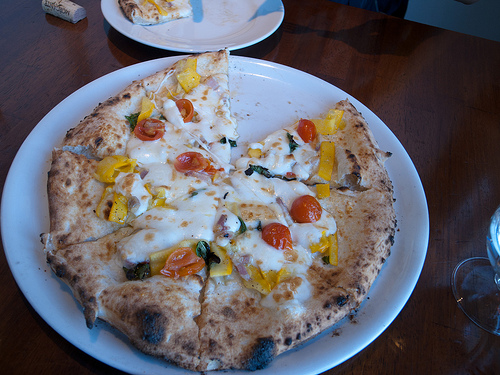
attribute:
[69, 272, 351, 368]
crust — piece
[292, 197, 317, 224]
tomato — red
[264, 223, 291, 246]
tomato — red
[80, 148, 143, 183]
peppers — yellow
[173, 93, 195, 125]
tomato — cherry, red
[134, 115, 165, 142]
tomato — cherry, red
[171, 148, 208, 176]
tomato — cherry, red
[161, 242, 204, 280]
tomato — red, cherry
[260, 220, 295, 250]
tomato — red, cherry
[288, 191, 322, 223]
tomato — red, cherry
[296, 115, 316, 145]
tomato — red, cherry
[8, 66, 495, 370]
plate — ceramic, white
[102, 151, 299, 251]
cheese — melted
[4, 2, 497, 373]
table — wood, shiny, stained, dark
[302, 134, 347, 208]
pepper — yellow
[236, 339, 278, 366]
area — burnt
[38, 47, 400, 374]
pizza — very tasty, not whole, piece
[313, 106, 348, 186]
peppers — topping, yellow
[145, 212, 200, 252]
mozzarella cheese — melted, white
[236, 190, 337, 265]
toppings — pizza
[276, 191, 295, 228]
onion — sliced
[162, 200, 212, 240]
cheese — topping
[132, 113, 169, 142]
tomato — red, half, cherry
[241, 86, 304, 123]
crumbs — small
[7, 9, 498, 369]
brown table — dark brown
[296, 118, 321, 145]
cherry tomato — red, half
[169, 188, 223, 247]
cheese — melted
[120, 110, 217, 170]
cheese — topping, melted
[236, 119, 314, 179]
cheese — melted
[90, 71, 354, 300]
cheese — melted